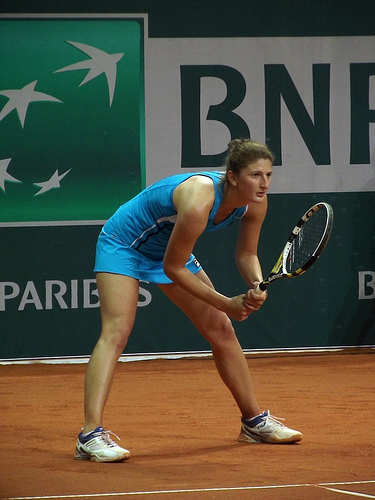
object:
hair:
[226, 137, 274, 190]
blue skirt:
[93, 230, 201, 280]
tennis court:
[0, 345, 374, 499]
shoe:
[237, 412, 304, 443]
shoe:
[72, 425, 131, 461]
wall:
[0, 0, 374, 367]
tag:
[104, 214, 172, 250]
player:
[74, 134, 303, 466]